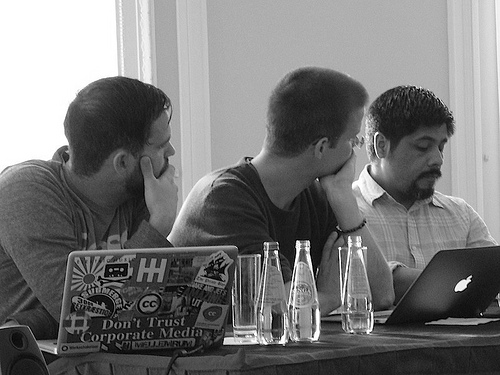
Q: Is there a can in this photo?
A: No, there are no cans.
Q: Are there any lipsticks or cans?
A: No, there are no cans or lipsticks.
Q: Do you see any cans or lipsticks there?
A: No, there are no cans or lipsticks.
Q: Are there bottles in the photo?
A: Yes, there is a bottle.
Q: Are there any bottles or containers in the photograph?
A: Yes, there is a bottle.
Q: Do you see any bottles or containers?
A: Yes, there is a bottle.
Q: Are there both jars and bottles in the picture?
A: No, there is a bottle but no jars.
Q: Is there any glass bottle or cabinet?
A: Yes, there is a glass bottle.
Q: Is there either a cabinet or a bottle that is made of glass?
A: Yes, the bottle is made of glass.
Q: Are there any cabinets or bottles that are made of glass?
A: Yes, the bottle is made of glass.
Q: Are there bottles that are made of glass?
A: Yes, there is a bottle that is made of glass.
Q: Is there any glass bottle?
A: Yes, there is a bottle that is made of glass.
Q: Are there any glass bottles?
A: Yes, there is a bottle that is made of glass.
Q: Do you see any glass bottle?
A: Yes, there is a bottle that is made of glass.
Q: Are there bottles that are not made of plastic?
A: Yes, there is a bottle that is made of glass.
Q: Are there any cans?
A: No, there are no cans.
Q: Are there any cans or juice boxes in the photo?
A: No, there are no cans or juice boxes.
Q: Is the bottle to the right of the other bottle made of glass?
A: Yes, the bottle is made of glass.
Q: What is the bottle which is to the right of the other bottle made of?
A: The bottle is made of glass.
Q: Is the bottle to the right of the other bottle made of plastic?
A: No, the bottle is made of glass.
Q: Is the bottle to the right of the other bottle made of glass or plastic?
A: The bottle is made of glass.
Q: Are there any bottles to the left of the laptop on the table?
A: Yes, there is a bottle to the left of the laptop.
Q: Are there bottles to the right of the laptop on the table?
A: No, the bottle is to the left of the laptop.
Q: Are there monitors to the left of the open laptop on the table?
A: No, there is a bottle to the left of the laptop.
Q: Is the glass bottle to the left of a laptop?
A: Yes, the bottle is to the left of a laptop.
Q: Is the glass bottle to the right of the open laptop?
A: No, the bottle is to the left of the laptop.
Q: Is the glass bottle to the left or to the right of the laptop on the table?
A: The bottle is to the left of the laptop.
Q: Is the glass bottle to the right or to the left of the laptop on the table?
A: The bottle is to the left of the laptop.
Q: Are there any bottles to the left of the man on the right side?
A: Yes, there is a bottle to the left of the man.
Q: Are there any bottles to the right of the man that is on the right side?
A: No, the bottle is to the left of the man.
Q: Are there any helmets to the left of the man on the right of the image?
A: No, there is a bottle to the left of the man.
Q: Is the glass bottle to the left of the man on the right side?
A: Yes, the bottle is to the left of the man.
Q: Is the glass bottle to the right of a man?
A: No, the bottle is to the left of a man.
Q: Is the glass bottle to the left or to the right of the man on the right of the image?
A: The bottle is to the left of the man.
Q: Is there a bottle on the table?
A: Yes, there is a bottle on the table.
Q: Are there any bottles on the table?
A: Yes, there is a bottle on the table.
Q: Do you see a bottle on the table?
A: Yes, there is a bottle on the table.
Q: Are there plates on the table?
A: No, there is a bottle on the table.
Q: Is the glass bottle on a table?
A: Yes, the bottle is on a table.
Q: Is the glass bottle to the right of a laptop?
A: Yes, the bottle is to the right of a laptop.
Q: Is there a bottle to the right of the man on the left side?
A: Yes, there is a bottle to the right of the man.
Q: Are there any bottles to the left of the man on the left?
A: No, the bottle is to the right of the man.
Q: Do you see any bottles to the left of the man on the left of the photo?
A: No, the bottle is to the right of the man.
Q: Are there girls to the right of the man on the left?
A: No, there is a bottle to the right of the man.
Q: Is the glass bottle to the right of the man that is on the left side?
A: Yes, the bottle is to the right of the man.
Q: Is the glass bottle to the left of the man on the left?
A: No, the bottle is to the right of the man.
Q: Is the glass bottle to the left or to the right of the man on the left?
A: The bottle is to the right of the man.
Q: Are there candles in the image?
A: No, there are no candles.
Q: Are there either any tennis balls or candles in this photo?
A: No, there are no candles or tennis balls.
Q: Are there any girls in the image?
A: No, there are no girls.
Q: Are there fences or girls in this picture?
A: No, there are no girls or fences.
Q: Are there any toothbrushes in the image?
A: No, there are no toothbrushes.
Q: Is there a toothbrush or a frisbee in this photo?
A: No, there are no toothbrushes or frisbees.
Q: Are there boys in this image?
A: No, there are no boys.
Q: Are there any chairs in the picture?
A: No, there are no chairs.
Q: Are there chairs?
A: No, there are no chairs.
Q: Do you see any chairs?
A: No, there are no chairs.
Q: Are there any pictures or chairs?
A: No, there are no chairs or pictures.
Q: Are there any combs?
A: No, there are no combs.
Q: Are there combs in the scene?
A: No, there are no combs.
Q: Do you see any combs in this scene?
A: No, there are no combs.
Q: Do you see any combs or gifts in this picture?
A: No, there are no combs or gifts.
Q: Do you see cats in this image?
A: No, there are no cats.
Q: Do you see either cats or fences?
A: No, there are no cats or fences.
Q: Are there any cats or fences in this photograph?
A: No, there are no cats or fences.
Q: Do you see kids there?
A: No, there are no kids.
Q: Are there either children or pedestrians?
A: No, there are no children or pedestrians.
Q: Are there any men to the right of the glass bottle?
A: Yes, there is a man to the right of the bottle.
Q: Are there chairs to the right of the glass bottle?
A: No, there is a man to the right of the bottle.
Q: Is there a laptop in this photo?
A: Yes, there is a laptop.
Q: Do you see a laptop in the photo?
A: Yes, there is a laptop.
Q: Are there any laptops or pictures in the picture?
A: Yes, there is a laptop.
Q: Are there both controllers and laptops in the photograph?
A: No, there is a laptop but no controllers.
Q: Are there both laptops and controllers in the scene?
A: No, there is a laptop but no controllers.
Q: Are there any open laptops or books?
A: Yes, there is an open laptop.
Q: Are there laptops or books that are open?
A: Yes, the laptop is open.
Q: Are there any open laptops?
A: Yes, there is an open laptop.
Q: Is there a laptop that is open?
A: Yes, there is a laptop that is open.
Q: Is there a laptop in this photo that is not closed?
A: Yes, there is a open laptop.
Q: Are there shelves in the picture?
A: No, there are no shelves.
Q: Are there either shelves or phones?
A: No, there are no shelves or phones.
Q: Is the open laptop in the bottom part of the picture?
A: Yes, the laptop is in the bottom of the image.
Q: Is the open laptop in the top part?
A: No, the laptop computer is in the bottom of the image.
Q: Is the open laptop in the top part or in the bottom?
A: The laptop is in the bottom of the image.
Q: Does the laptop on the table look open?
A: Yes, the laptop is open.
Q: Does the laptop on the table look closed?
A: No, the laptop is open.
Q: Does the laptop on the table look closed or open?
A: The laptop computer is open.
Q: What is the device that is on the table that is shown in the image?
A: The device is a laptop.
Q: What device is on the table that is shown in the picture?
A: The device is a laptop.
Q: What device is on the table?
A: The device is a laptop.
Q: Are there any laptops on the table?
A: Yes, there is a laptop on the table.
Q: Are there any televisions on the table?
A: No, there is a laptop on the table.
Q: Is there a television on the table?
A: No, there is a laptop on the table.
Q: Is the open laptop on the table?
A: Yes, the laptop is on the table.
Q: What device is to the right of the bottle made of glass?
A: The device is a laptop.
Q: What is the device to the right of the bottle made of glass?
A: The device is a laptop.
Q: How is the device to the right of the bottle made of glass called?
A: The device is a laptop.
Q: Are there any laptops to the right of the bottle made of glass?
A: Yes, there is a laptop to the right of the bottle.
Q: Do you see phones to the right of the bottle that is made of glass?
A: No, there is a laptop to the right of the bottle.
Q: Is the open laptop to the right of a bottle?
A: Yes, the laptop is to the right of a bottle.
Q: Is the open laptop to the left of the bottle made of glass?
A: No, the laptop computer is to the right of the bottle.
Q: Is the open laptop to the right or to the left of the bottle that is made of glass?
A: The laptop computer is to the right of the bottle.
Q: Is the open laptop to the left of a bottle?
A: No, the laptop is to the right of a bottle.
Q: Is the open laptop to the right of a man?
A: Yes, the laptop is to the right of a man.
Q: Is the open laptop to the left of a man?
A: No, the laptop is to the right of a man.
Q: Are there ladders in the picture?
A: No, there are no ladders.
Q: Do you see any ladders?
A: No, there are no ladders.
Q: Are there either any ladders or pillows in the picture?
A: No, there are no ladders or pillows.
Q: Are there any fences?
A: No, there are no fences.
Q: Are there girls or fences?
A: No, there are no fences or girls.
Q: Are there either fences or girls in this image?
A: No, there are no fences or girls.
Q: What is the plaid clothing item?
A: The clothing item is a shirt.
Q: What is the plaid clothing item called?
A: The clothing item is a shirt.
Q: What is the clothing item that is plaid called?
A: The clothing item is a shirt.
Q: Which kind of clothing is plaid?
A: The clothing is a shirt.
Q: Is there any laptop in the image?
A: Yes, there is a laptop.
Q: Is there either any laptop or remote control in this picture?
A: Yes, there is a laptop.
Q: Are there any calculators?
A: No, there are no calculators.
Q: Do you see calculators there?
A: No, there are no calculators.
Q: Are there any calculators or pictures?
A: No, there are no calculators or pictures.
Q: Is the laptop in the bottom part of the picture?
A: Yes, the laptop is in the bottom of the image.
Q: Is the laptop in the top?
A: No, the laptop is in the bottom of the image.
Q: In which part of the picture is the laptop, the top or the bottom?
A: The laptop is in the bottom of the image.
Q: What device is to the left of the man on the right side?
A: The device is a laptop.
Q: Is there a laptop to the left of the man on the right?
A: Yes, there is a laptop to the left of the man.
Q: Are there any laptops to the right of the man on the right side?
A: No, the laptop is to the left of the man.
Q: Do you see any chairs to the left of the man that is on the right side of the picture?
A: No, there is a laptop to the left of the man.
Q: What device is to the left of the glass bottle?
A: The device is a laptop.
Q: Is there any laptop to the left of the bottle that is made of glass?
A: Yes, there is a laptop to the left of the bottle.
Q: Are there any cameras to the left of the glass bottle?
A: No, there is a laptop to the left of the bottle.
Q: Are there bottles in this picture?
A: Yes, there is a bottle.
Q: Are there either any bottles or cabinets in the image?
A: Yes, there is a bottle.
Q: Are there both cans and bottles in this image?
A: No, there is a bottle but no cans.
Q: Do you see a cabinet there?
A: No, there are no cabinets.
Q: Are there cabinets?
A: No, there are no cabinets.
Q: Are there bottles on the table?
A: Yes, there is a bottle on the table.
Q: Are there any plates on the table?
A: No, there is a bottle on the table.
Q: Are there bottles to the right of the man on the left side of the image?
A: Yes, there is a bottle to the right of the man.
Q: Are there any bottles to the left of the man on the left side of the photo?
A: No, the bottle is to the right of the man.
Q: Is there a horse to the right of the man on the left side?
A: No, there is a bottle to the right of the man.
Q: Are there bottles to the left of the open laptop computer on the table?
A: Yes, there is a bottle to the left of the laptop computer.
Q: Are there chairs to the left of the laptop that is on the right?
A: No, there is a bottle to the left of the laptop computer.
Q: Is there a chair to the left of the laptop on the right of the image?
A: No, there is a bottle to the left of the laptop computer.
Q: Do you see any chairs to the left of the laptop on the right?
A: No, there is a bottle to the left of the laptop computer.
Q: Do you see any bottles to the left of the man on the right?
A: Yes, there is a bottle to the left of the man.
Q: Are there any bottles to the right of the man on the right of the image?
A: No, the bottle is to the left of the man.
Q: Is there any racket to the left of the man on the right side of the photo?
A: No, there is a bottle to the left of the man.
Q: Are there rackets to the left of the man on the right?
A: No, there is a bottle to the left of the man.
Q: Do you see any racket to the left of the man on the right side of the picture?
A: No, there is a bottle to the left of the man.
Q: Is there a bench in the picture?
A: No, there are no benches.